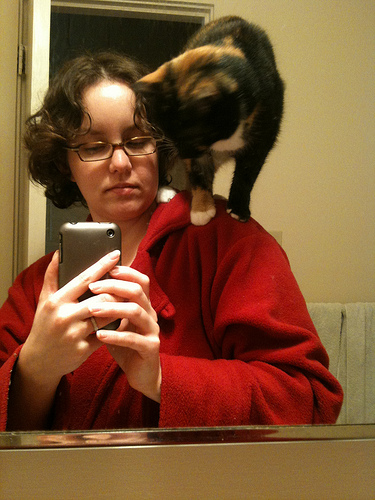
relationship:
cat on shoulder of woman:
[137, 14, 285, 227] [2, 51, 343, 427]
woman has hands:
[2, 51, 343, 427] [25, 250, 162, 395]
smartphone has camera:
[57, 220, 123, 336] [105, 227, 117, 241]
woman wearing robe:
[2, 51, 343, 427] [2, 188, 347, 428]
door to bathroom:
[16, 0, 46, 280] [0, 0, 372, 499]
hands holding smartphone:
[25, 250, 162, 395] [57, 220, 123, 336]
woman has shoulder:
[2, 51, 343, 427] [153, 183, 266, 252]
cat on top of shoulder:
[137, 14, 285, 227] [153, 183, 266, 252]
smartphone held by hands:
[57, 220, 123, 336] [25, 250, 162, 395]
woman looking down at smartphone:
[2, 51, 343, 427] [57, 220, 123, 336]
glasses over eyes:
[55, 133, 165, 166] [85, 140, 146, 154]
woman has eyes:
[2, 51, 343, 427] [85, 140, 146, 154]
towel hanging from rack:
[302, 302, 375, 427] [304, 300, 374, 318]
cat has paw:
[137, 14, 285, 227] [188, 191, 215, 227]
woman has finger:
[2, 51, 343, 427] [81, 306, 118, 335]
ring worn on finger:
[88, 312, 99, 334] [81, 306, 118, 335]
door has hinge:
[16, 0, 46, 280] [13, 41, 27, 77]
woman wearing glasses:
[2, 51, 343, 427] [55, 133, 165, 166]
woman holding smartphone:
[2, 51, 343, 427] [57, 220, 123, 336]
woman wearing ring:
[2, 51, 343, 427] [88, 312, 99, 334]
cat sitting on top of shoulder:
[137, 14, 285, 227] [153, 183, 266, 252]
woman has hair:
[2, 51, 343, 427] [23, 50, 179, 208]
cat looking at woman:
[137, 14, 285, 227] [2, 51, 343, 427]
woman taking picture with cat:
[2, 51, 343, 427] [137, 14, 285, 227]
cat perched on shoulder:
[137, 14, 285, 227] [153, 183, 266, 252]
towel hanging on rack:
[302, 302, 375, 427] [304, 300, 374, 318]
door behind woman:
[16, 0, 46, 280] [2, 51, 343, 427]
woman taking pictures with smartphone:
[2, 51, 343, 427] [57, 220, 123, 336]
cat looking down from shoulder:
[137, 14, 285, 227] [153, 183, 266, 252]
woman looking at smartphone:
[2, 51, 343, 427] [57, 220, 123, 336]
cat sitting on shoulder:
[137, 14, 285, 227] [153, 183, 266, 252]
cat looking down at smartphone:
[137, 14, 285, 227] [57, 220, 123, 336]